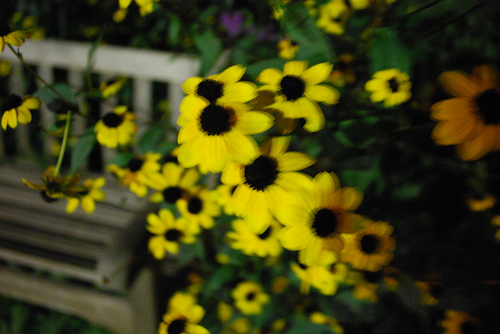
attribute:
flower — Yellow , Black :
[101, 67, 129, 98]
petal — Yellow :
[202, 140, 222, 173]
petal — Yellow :
[226, 132, 252, 157]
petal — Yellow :
[236, 110, 271, 130]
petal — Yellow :
[173, 122, 198, 142]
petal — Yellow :
[178, 134, 198, 163]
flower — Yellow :
[143, 163, 201, 201]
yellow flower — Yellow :
[176, 186, 221, 233]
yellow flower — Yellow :
[220, 135, 317, 232]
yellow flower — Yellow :
[255, 61, 335, 132]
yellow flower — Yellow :
[93, 105, 135, 146]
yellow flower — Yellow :
[365, 67, 411, 106]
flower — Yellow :
[428, 64, 499, 166]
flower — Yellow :
[365, 67, 414, 109]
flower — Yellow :
[252, 56, 343, 133]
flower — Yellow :
[174, 62, 260, 117]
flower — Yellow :
[173, 97, 274, 174]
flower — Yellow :
[216, 129, 318, 231]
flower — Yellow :
[271, 169, 364, 261]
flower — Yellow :
[336, 215, 398, 275]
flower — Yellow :
[91, 102, 136, 147]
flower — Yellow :
[1, 90, 43, 130]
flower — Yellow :
[21, 166, 84, 202]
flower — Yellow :
[1, 23, 34, 53]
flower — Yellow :
[60, 175, 105, 212]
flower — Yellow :
[108, 148, 158, 178]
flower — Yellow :
[139, 159, 201, 202]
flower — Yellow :
[173, 183, 220, 230]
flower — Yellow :
[143, 207, 199, 262]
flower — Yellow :
[229, 281, 270, 316]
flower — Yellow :
[226, 210, 288, 255]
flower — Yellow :
[156, 290, 208, 332]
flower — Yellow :
[441, 307, 483, 332]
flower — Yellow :
[86, 90, 149, 162]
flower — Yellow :
[180, 102, 272, 174]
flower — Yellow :
[269, 183, 364, 267]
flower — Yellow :
[92, 103, 142, 150]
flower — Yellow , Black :
[146, 192, 213, 258]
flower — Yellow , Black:
[250, 135, 365, 244]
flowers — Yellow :
[178, 101, 272, 173]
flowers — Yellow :
[223, 137, 310, 233]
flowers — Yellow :
[258, 59, 334, 134]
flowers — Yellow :
[112, 153, 162, 200]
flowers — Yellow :
[87, 104, 140, 149]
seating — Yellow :
[3, 43, 203, 333]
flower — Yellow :
[161, 77, 401, 255]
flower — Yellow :
[94, 104, 136, 152]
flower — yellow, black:
[360, 63, 422, 119]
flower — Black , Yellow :
[21, 152, 128, 224]